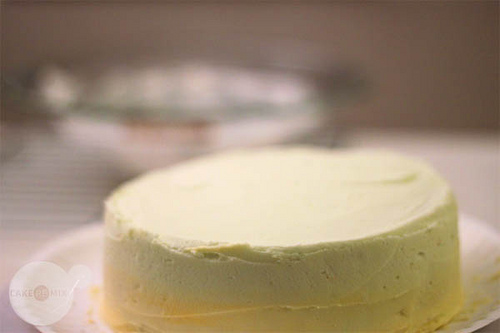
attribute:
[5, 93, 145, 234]
grate — for cooling baked goods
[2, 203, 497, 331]
dish — white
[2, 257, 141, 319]
logo — in middle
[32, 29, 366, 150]
picture — blurred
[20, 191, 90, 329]
plate — white